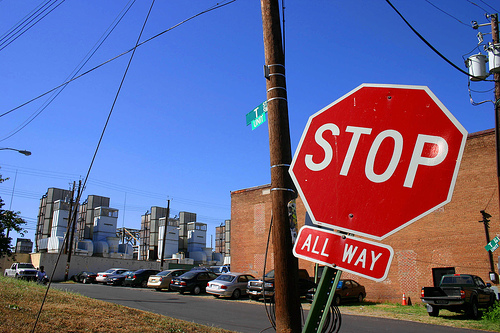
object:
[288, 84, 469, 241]
sign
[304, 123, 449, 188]
stop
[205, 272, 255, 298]
car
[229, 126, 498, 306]
building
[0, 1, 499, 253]
sky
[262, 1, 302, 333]
post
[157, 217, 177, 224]
container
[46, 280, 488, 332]
road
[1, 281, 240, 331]
grass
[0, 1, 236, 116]
telephone wires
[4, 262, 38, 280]
truck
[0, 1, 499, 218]
distance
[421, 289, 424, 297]
tail light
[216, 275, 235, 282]
rear window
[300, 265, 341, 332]
pole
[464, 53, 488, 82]
electric transformer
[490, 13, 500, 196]
pole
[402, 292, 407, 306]
traffic cone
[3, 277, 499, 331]
ground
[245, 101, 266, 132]
sign